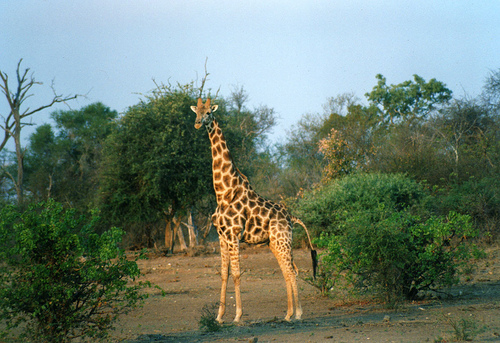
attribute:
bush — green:
[303, 204, 484, 311]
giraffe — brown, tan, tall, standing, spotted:
[184, 94, 324, 325]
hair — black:
[307, 248, 320, 277]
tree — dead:
[1, 53, 33, 199]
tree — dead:
[2, 68, 79, 151]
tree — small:
[2, 192, 162, 337]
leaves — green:
[92, 237, 122, 264]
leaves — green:
[121, 120, 165, 165]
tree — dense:
[98, 88, 263, 260]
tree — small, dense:
[286, 173, 479, 304]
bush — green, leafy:
[292, 164, 481, 304]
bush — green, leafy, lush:
[2, 190, 162, 338]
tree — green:
[89, 78, 267, 261]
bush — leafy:
[0, 202, 130, 341]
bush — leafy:
[296, 173, 484, 330]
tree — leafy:
[105, 85, 200, 236]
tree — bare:
[1, 41, 64, 170]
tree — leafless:
[5, 60, 75, 202]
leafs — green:
[389, 205, 417, 234]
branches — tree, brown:
[29, 100, 44, 121]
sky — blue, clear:
[311, 20, 377, 54]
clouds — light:
[249, 10, 319, 30]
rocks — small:
[323, 326, 337, 336]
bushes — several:
[309, 129, 484, 306]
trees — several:
[53, 90, 191, 240]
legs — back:
[264, 224, 326, 334]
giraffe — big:
[176, 80, 335, 335]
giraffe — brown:
[176, 100, 322, 319]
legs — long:
[199, 223, 309, 337]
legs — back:
[253, 220, 317, 322]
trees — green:
[30, 92, 178, 300]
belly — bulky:
[241, 223, 265, 245]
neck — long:
[187, 123, 241, 193]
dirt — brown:
[0, 243, 499, 342]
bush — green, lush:
[290, 169, 490, 308]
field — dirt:
[2, 241, 499, 341]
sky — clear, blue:
[0, 1, 498, 168]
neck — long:
[205, 119, 249, 201]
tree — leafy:
[364, 72, 453, 127]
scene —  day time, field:
[9, 1, 484, 341]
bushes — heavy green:
[53, 93, 456, 292]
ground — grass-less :
[172, 241, 216, 283]